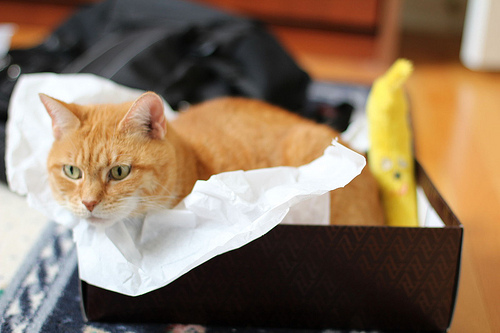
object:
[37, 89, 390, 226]
cat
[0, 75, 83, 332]
rug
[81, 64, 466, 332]
box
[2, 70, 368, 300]
paper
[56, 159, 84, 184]
eye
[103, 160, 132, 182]
eye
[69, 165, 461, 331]
shoe box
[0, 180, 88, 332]
carpet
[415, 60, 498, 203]
flooring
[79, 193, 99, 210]
nose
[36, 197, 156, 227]
whiskers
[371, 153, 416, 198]
face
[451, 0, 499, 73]
door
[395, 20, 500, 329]
floor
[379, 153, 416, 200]
label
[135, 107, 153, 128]
whiskers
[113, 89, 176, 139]
ear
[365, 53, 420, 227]
banana